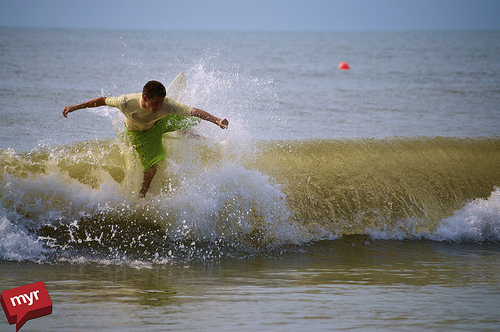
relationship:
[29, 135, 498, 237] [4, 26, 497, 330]
wave crashing in water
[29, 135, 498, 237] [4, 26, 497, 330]
wave in water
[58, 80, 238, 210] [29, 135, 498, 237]
man hit by wave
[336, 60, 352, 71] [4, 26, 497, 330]
buoy in water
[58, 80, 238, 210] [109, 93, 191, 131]
man wearing shirt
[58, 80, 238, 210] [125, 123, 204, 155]
man wearing shorts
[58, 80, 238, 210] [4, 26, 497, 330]
man in water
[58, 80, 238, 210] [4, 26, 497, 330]
man bending in water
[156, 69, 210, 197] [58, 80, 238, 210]
surfboard behind man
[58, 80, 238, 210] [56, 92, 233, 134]
man extends arms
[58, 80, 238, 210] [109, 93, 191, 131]
man in shirt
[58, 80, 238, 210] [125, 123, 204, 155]
man in shorts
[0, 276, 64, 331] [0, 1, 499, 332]
logo in picture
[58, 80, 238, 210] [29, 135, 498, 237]
man riding wave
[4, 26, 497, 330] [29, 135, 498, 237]
water near wave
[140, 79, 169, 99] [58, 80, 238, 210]
hair on man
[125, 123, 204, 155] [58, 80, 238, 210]
shorts on man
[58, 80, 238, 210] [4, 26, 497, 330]
man looking at water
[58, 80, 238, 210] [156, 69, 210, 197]
man on surfboard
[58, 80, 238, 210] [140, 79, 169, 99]
man has hair